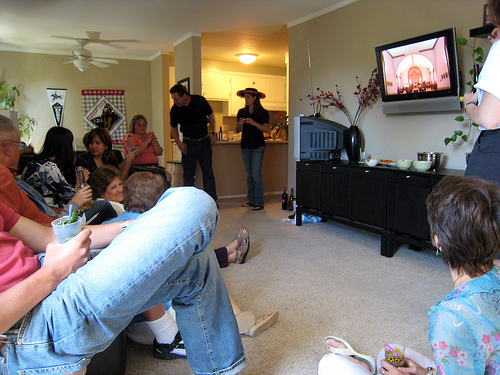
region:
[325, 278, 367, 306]
carpet on the floor.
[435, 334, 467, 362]
flower pattern on shirt.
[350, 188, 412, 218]
black piece of furniture.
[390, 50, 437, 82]
image on the screen.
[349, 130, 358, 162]
vase on the furniture.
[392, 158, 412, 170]
bowl on the furniture.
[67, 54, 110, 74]
fan on the ceiling.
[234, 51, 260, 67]
light on the ceiling.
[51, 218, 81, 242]
cup in man's hand.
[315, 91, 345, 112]
flowers in the vase.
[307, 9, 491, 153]
The television is hanging on the wall.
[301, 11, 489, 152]
The television is on.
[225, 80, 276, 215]
The woman is wearing a hat.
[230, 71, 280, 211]
The woman is wearing a shirt.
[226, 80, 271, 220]
The woman is wearing pants.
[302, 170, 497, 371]
The woman is sitting on the floor.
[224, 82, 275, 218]
The woman is standing.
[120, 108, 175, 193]
The woman is sitting.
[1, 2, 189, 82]
The ceiling fan is white.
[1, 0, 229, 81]
The ceiling fan is off.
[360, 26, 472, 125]
television on a wall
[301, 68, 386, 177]
plant in a black vase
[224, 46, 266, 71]
light illuminated on ceiling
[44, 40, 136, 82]
ceiling fan in living room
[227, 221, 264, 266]
sandals of a woman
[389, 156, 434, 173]
bowls on a counter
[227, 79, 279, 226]
woman standing with a hat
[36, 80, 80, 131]
banner on the wall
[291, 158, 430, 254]
entertainment center against wall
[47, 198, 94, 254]
cup in man's hand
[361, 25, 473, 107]
A tv screen with a program on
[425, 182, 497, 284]
The back of a person's head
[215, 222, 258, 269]
Teh feet of a person with sandals on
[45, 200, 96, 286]
A hand holding a plastic cup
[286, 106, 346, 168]
The side of a desk top tv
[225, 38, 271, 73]
A lit ceiling light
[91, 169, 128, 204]
The face of a smiling woman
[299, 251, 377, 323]
Ivory rugs on the floor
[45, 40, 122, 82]
A white ceiling fan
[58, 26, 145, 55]
The shadow of a fan on the ceiling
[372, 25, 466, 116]
Wall mounted flat screen television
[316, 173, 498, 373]
Woman looking at the television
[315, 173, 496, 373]
Woman holding a beverage in her lap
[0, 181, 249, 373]
Man in blue jeans holding a plastic cup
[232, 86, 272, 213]
Woman wearing a black shirt and blue jeans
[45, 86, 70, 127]
Triangular sports team banner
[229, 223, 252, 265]
Gray sandals on crossed feet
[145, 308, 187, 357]
White sock under a black sandal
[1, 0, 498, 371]
Friends hanging out in a living room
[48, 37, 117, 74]
White ceiling fan